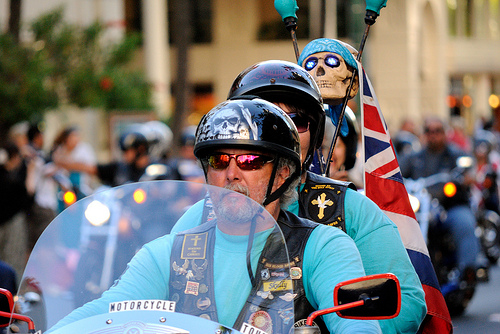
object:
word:
[108, 299, 177, 313]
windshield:
[5, 180, 293, 334]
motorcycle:
[0, 180, 400, 332]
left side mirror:
[306, 272, 401, 325]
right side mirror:
[0, 287, 35, 333]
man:
[43, 97, 381, 333]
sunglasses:
[202, 151, 276, 171]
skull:
[298, 36, 362, 102]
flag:
[353, 55, 454, 333]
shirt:
[40, 224, 380, 333]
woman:
[171, 60, 428, 333]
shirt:
[172, 174, 428, 333]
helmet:
[192, 99, 303, 224]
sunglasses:
[287, 112, 316, 133]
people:
[0, 122, 35, 263]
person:
[399, 120, 490, 285]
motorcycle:
[394, 155, 479, 316]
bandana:
[298, 37, 358, 70]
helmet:
[227, 58, 326, 150]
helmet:
[325, 105, 360, 169]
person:
[321, 104, 366, 193]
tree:
[0, 7, 156, 130]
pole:
[327, 0, 385, 176]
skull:
[211, 109, 241, 140]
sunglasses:
[424, 127, 442, 136]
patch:
[180, 231, 209, 260]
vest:
[167, 208, 331, 333]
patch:
[183, 281, 199, 297]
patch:
[248, 310, 273, 333]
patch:
[259, 255, 300, 270]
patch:
[306, 189, 336, 221]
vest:
[200, 171, 358, 234]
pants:
[437, 206, 479, 272]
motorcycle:
[43, 163, 177, 308]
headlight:
[406, 193, 420, 213]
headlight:
[83, 200, 109, 226]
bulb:
[361, 1, 387, 24]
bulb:
[273, 2, 300, 31]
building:
[125, 2, 500, 130]